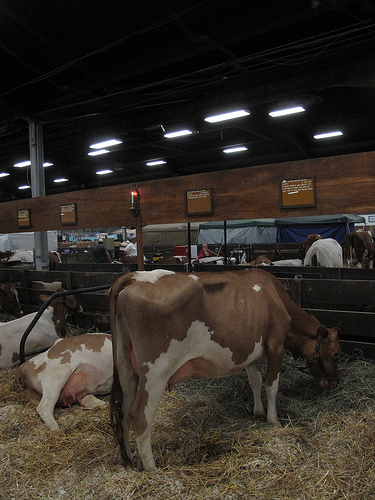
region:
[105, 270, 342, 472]
Cow standing and eating hay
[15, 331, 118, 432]
White and brown cow laying in the hay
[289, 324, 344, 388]
Brown harness over cow's head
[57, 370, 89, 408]
Udders under cow's belly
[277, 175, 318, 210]
Sign hanging on the wall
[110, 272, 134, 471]
Long tail of cow nearly touching the ground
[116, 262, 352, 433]
cow is eating hay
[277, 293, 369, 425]
cow is eating hay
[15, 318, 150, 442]
cow is sitting on the hay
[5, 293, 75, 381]
cow is sitting on the hay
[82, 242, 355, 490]
this is a cow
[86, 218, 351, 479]
the cow is brown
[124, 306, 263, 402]
white spots on cow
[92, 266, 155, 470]
tail on the cow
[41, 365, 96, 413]
utters on the cow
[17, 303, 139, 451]
cow is laying down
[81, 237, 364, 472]
cow is standing up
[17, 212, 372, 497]
cows in a stall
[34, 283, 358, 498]
hay in the stall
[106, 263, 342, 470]
A cow eating hay.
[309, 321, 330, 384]
A bridle on the cow.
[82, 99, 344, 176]
Lights hanging from the ceiling.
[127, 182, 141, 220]
A light on the wood wall.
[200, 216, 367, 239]
Two tents in the distance.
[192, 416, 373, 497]
Hay on the ground.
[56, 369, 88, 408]
Utters on the cow.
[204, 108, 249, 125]
overhead fluorescent lighting in the barn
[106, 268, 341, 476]
a brown and white milk cow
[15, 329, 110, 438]
a collapsed milk cow on its side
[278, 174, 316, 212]
overhead monitor screens in the barn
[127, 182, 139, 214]
a red light monitor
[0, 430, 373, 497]
hay covering the cow stalls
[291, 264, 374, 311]
a wooden fence along the cow stall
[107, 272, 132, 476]
long tail of the brown cow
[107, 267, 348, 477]
cow standing up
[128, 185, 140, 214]
red light on a wall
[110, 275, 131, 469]
tail of a standing cow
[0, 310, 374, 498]
hay in a pen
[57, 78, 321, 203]
lights on the celing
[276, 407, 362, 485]
hay on the ground